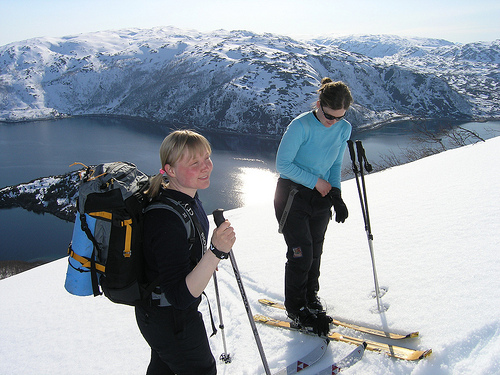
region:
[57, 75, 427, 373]
Two women on skis.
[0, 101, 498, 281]
A lake of water behind the women.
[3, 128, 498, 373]
Snow on the ground.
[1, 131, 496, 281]
A ledge behind the women.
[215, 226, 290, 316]
Ski tracks in the snow.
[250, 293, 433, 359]
A pair of yellow skis.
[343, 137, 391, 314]
Ski poles poked into the snow.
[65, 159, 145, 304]
A blue and black backpack with yellow straps.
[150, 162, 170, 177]
A red band in the woman's hair.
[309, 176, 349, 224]
A black glove on one hand.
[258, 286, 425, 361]
a woman using snowboard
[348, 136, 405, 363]
snow board with snow stick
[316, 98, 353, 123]
a woman wearing black color eye glasses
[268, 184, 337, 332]
a woman wearing black color jean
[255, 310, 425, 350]
brown color snow board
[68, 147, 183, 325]
a woman holding backbag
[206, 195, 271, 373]
a woman holding snow stick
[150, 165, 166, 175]
a woman wearing pink color band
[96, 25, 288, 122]
mountain covred with snow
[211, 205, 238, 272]
a handle of the snow stick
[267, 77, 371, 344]
a woman wearing a blue shirt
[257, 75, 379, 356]
a woman wearing black snow pants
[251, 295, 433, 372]
a pair of yellow skis on the ground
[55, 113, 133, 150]
calm waters of the lake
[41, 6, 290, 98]
snowy mountains in the background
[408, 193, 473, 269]
smooth snow on the mountain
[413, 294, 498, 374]
tracks in the snow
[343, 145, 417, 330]
a pair of ski poles planted in the ground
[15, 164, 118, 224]
a small island in the lake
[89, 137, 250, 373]
a woman wearing a black snow suit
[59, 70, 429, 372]
two women on skis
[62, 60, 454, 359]
two women are skiing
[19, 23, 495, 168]
the fjord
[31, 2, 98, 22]
the sky is clear and blue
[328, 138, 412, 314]
the ski poles in the snow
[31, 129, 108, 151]
the water is calm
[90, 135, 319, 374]
the woman holding the ski poles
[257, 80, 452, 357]
the woman on yellow skis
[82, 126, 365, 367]
the woman on silver skis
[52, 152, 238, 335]
woman with backpack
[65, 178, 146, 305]
a young woman carrying a backpack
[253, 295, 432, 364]
man wearing a pair of yellow skis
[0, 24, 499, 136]
snowy rocky mountains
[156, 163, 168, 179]
a pink elastic in young woman's hair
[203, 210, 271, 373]
a young woman holding ski poles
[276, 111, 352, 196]
a woman wearing a blue sweater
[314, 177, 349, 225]
a woman putting on some black gloves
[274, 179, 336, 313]
woman wearing black ski pants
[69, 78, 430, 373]
two women skying in the snow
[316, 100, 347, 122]
woman wearing a pair of black sunglasses